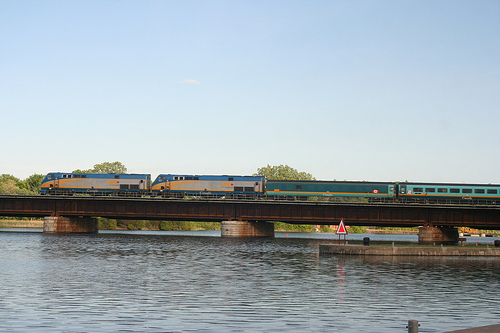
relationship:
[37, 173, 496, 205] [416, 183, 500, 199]
train has windows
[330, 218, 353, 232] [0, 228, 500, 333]
sign in lake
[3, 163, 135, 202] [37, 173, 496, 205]
tree behind train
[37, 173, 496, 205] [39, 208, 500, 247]
train on bridge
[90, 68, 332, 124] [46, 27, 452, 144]
clouds in sky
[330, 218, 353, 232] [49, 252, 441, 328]
sign by water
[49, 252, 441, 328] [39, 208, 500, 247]
water by bridge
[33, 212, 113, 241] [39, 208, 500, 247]
pillars by bridge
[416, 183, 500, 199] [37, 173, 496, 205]
windows on train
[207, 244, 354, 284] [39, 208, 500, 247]
shadow under bridge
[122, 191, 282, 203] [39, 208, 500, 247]
railing on bridge